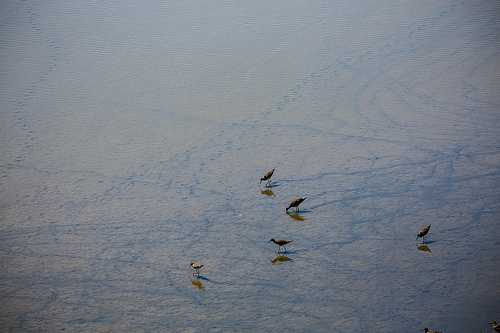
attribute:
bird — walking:
[284, 194, 319, 216]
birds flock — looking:
[184, 165, 431, 289]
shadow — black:
[258, 185, 276, 200]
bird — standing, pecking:
[279, 194, 308, 227]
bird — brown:
[255, 235, 325, 256]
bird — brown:
[179, 242, 211, 276]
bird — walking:
[166, 250, 243, 281]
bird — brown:
[413, 224, 432, 242]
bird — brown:
[256, 159, 343, 306]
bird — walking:
[413, 222, 435, 242]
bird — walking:
[412, 220, 431, 245]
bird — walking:
[264, 237, 294, 254]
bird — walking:
[256, 169, 283, 186]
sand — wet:
[54, 278, 488, 321]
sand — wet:
[24, 233, 497, 324]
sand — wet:
[7, 245, 496, 333]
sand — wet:
[15, 205, 492, 333]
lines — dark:
[29, 243, 188, 306]